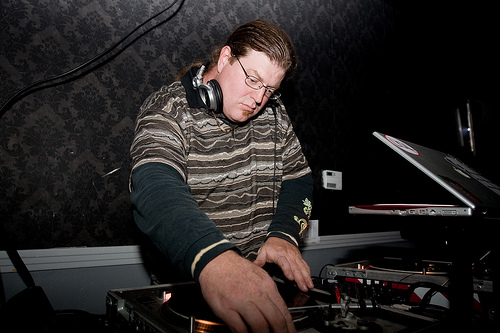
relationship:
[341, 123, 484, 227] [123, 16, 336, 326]
laptop near man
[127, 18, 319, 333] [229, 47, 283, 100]
man wearing eyeglasses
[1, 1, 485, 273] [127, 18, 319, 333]
wall behind man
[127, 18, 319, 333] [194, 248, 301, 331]
man has hand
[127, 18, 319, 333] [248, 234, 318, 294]
man has hand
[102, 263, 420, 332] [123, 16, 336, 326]
record player in front of man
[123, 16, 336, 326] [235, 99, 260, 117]
man has mouth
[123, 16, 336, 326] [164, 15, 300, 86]
man has hair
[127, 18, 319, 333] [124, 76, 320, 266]
man wearing shirt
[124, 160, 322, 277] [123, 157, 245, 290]
shirt has sleeve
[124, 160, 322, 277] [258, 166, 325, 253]
shirt has sleeve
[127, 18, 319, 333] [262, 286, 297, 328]
man has finger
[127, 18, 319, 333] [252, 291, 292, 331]
man has finger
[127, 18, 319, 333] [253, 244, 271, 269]
man has finger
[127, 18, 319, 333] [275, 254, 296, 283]
man has finger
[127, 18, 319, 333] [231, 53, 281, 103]
man wearing eyeglasses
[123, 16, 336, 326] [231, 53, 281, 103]
man wearing eyeglasses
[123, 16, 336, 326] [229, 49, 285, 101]
man wearing eyeglasses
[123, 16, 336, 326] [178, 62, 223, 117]
man with headphones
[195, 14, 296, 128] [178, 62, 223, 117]
head with headphones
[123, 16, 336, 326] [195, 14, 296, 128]
man with head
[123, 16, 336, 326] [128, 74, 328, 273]
man wearing shirt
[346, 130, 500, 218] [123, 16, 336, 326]
laptop in front of man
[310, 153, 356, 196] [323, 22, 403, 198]
control switch on wall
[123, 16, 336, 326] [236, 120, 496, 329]
man using dj equipment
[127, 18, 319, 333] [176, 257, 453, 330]
man using record player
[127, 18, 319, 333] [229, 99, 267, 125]
man with goatee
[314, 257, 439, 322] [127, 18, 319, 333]
wires on man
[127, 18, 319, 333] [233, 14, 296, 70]
man with brown hair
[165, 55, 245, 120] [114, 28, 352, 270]
headphones on man